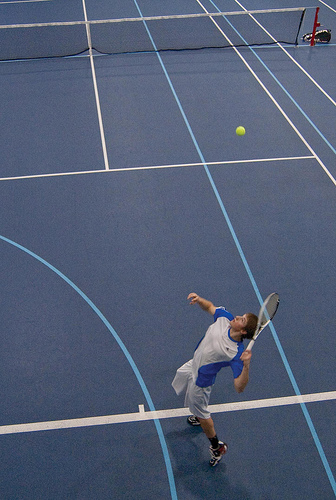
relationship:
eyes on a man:
[238, 315, 245, 325] [171, 291, 260, 470]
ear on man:
[238, 327, 249, 334] [171, 291, 260, 470]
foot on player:
[202, 436, 231, 471] [171, 291, 258, 473]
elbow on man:
[234, 384, 244, 393] [171, 291, 260, 470]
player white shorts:
[168, 278, 281, 473] [168, 360, 215, 421]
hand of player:
[184, 290, 198, 306] [171, 291, 258, 473]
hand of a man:
[184, 290, 198, 306] [162, 285, 259, 475]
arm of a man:
[176, 278, 226, 320] [161, 269, 279, 480]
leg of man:
[194, 399, 219, 448] [171, 291, 260, 470]